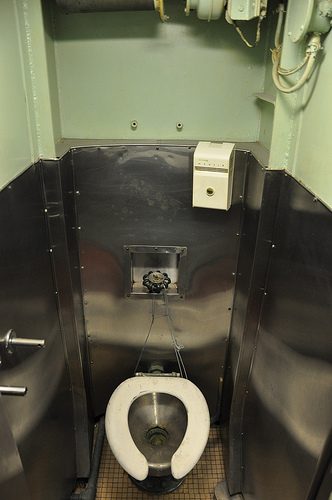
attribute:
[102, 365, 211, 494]
toilet bowl — rusty, old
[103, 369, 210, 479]
toilet seat — white, worn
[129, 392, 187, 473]
steel bowl — stainless steel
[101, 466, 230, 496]
tile — small, square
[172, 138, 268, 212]
dispenser — white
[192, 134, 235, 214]
box — white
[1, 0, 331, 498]
bathroom — metal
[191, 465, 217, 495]
tile — small, square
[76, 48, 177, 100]
wall — metal, old, bathroom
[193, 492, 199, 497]
tile — small, square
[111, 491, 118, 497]
tile — small, square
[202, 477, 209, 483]
tile — small, square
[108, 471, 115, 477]
tile — small, square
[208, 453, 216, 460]
tile — small, square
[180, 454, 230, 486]
tile — square, small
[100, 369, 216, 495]
toilet — waterless, metal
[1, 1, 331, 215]
green walls — painted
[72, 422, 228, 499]
tile — small, ceramic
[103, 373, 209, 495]
bowl — stainless steel, toilet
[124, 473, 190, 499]
base — metal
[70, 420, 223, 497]
floor — dirty, brown, tile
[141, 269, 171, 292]
valve — black, metal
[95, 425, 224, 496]
floor — tiled